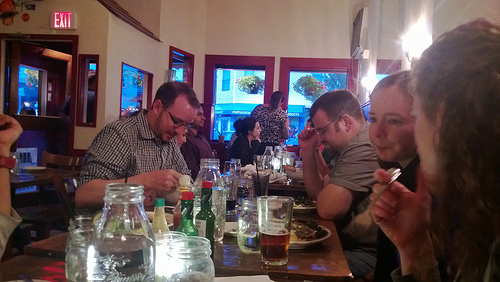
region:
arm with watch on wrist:
[0, 111, 25, 258]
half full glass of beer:
[256, 194, 291, 266]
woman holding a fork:
[346, 18, 497, 280]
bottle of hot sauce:
[194, 180, 215, 257]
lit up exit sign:
[52, 10, 74, 29]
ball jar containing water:
[86, 178, 156, 279]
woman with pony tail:
[248, 89, 291, 156]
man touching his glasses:
[295, 86, 380, 277]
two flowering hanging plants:
[234, 71, 329, 99]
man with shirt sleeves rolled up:
[73, 78, 200, 213]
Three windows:
[150, 38, 396, 165]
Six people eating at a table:
[53, 51, 498, 268]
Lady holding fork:
[357, 30, 494, 280]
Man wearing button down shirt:
[62, 64, 224, 229]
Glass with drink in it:
[239, 191, 311, 272]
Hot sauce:
[154, 175, 231, 268]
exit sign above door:
[36, 10, 101, 46]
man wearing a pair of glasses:
[250, 91, 391, 226]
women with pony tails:
[222, 75, 302, 146]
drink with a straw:
[223, 151, 295, 211]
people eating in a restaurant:
[5, 13, 497, 279]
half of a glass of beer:
[252, 185, 298, 271]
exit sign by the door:
[42, 6, 87, 37]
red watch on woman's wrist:
[0, 145, 22, 179]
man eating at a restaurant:
[59, 73, 209, 204]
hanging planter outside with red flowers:
[286, 73, 331, 103]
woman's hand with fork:
[342, 160, 422, 260]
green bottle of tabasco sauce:
[189, 173, 224, 273]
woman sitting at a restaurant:
[225, 115, 272, 170]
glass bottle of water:
[79, 177, 157, 279]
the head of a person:
[145, 67, 199, 141]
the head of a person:
[187, 97, 208, 134]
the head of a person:
[234, 110, 264, 142]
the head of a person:
[268, 90, 289, 107]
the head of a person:
[305, 83, 367, 150]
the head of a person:
[361, 65, 425, 176]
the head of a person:
[408, 20, 494, 153]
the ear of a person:
[339, 112, 356, 133]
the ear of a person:
[151, 99, 161, 112]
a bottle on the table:
[194, 173, 219, 254]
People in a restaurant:
[11, 18, 496, 280]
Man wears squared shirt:
[70, 76, 225, 211]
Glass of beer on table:
[246, 186, 303, 271]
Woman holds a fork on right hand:
[334, 16, 497, 272]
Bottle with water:
[85, 170, 162, 279]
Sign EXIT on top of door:
[42, 5, 79, 37]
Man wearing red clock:
[0, 106, 33, 218]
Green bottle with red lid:
[194, 172, 227, 261]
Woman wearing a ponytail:
[241, 78, 291, 130]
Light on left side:
[388, 18, 432, 54]